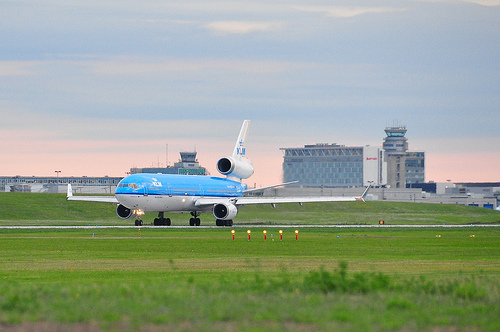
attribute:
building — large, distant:
[278, 142, 386, 189]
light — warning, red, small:
[292, 227, 300, 239]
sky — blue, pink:
[0, 0, 498, 190]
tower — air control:
[383, 123, 409, 194]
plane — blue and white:
[112, 120, 299, 229]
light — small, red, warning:
[277, 228, 287, 245]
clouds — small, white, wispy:
[187, 3, 402, 44]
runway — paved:
[2, 222, 496, 227]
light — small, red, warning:
[226, 226, 236, 246]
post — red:
[291, 224, 299, 240]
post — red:
[273, 224, 284, 238]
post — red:
[258, 225, 269, 240]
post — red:
[242, 224, 254, 243]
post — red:
[229, 227, 241, 243]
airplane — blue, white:
[70, 112, 301, 234]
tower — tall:
[384, 125, 409, 187]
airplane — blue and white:
[80, 133, 274, 238]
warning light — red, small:
[259, 225, 274, 238]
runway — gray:
[4, 214, 499, 231]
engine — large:
[219, 156, 254, 177]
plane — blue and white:
[61, 113, 374, 228]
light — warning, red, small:
[218, 206, 310, 246]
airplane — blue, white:
[64, 117, 373, 228]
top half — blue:
[115, 175, 245, 201]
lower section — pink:
[0, 140, 498, 190]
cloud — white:
[149, 12, 273, 39]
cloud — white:
[270, 1, 410, 21]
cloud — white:
[3, 51, 326, 87]